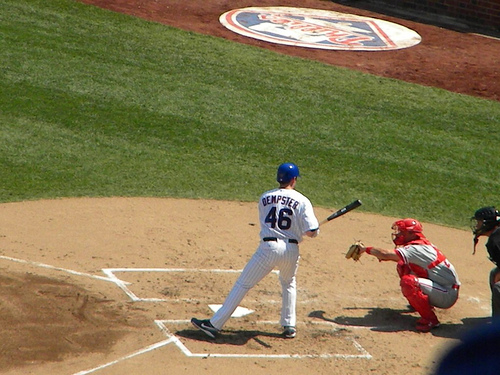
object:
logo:
[217, 6, 422, 53]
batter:
[189, 162, 319, 339]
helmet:
[276, 161, 303, 185]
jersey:
[258, 186, 319, 245]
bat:
[318, 199, 363, 228]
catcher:
[344, 217, 461, 333]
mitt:
[341, 238, 366, 267]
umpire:
[469, 205, 500, 328]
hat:
[469, 206, 500, 238]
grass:
[0, 0, 500, 240]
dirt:
[77, 0, 500, 104]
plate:
[207, 304, 256, 319]